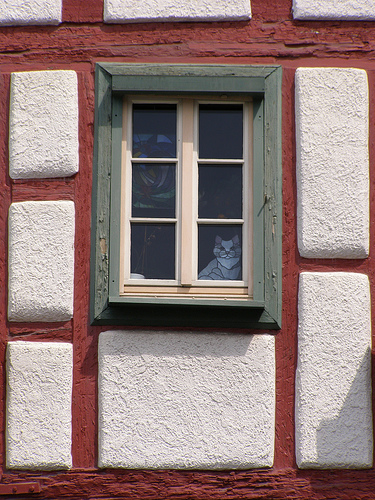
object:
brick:
[293, 62, 372, 258]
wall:
[0, 0, 375, 499]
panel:
[131, 161, 175, 218]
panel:
[197, 222, 242, 279]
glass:
[197, 103, 242, 162]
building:
[0, 0, 374, 497]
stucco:
[88, 329, 274, 473]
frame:
[92, 53, 282, 97]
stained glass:
[131, 161, 177, 218]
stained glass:
[200, 222, 242, 278]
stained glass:
[130, 224, 174, 279]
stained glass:
[199, 163, 242, 219]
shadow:
[94, 82, 271, 142]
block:
[295, 61, 370, 262]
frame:
[97, 88, 267, 308]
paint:
[262, 190, 279, 269]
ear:
[215, 233, 223, 244]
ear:
[232, 232, 240, 245]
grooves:
[0, 473, 375, 498]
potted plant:
[129, 222, 176, 280]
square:
[8, 68, 81, 181]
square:
[94, 327, 279, 468]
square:
[4, 340, 74, 473]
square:
[295, 268, 374, 470]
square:
[293, 65, 372, 261]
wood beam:
[13, 0, 83, 68]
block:
[296, 273, 373, 469]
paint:
[96, 233, 109, 258]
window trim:
[104, 273, 264, 307]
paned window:
[109, 87, 266, 308]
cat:
[199, 235, 243, 280]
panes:
[131, 102, 243, 282]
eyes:
[220, 246, 224, 251]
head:
[212, 234, 241, 269]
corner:
[118, 267, 141, 295]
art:
[132, 128, 180, 216]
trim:
[0, 0, 374, 498]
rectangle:
[5, 338, 73, 470]